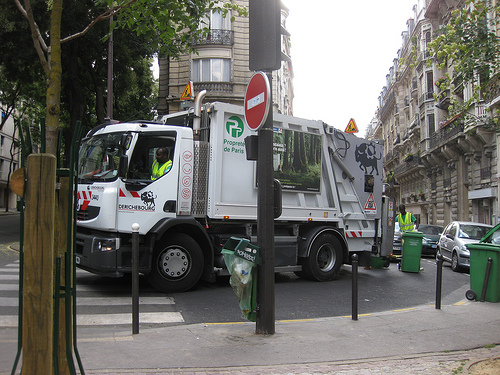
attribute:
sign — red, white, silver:
[238, 66, 274, 134]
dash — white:
[242, 88, 268, 110]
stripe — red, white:
[117, 185, 145, 200]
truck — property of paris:
[68, 86, 395, 287]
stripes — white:
[74, 272, 187, 333]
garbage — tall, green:
[396, 229, 424, 275]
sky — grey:
[294, 3, 384, 119]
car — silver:
[434, 217, 490, 276]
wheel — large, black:
[147, 221, 208, 290]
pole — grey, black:
[246, 2, 286, 333]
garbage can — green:
[460, 221, 498, 304]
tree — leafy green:
[4, 3, 205, 170]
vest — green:
[147, 161, 175, 182]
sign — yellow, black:
[341, 115, 361, 137]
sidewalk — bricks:
[341, 358, 470, 375]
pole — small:
[128, 223, 145, 335]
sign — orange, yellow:
[179, 80, 203, 109]